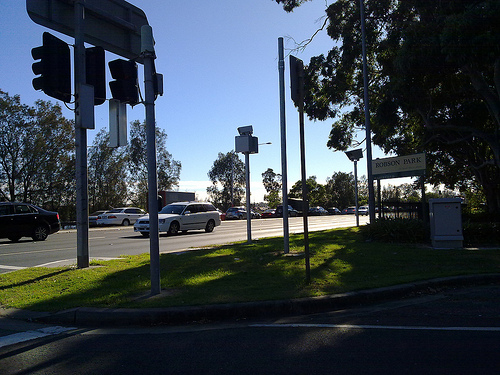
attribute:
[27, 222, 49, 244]
tire — black, round, rubber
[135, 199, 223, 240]
car — white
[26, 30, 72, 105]
light — black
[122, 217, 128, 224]
black tire — rubber, round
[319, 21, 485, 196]
tree — green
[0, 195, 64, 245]
car — black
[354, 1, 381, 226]
pole — metal, tall, silver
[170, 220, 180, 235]
tire — round, black, rubber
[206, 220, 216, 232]
tire — round, black, rubber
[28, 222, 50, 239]
tire — round, black, rubber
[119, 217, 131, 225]
tire — round, black, rubber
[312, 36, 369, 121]
leaves — green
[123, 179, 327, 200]
cloud — white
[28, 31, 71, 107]
light — black, street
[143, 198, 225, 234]
car — white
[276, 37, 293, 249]
pole — tall, silver, metal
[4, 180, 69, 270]
car — dark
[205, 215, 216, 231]
tire — rubber, round, black